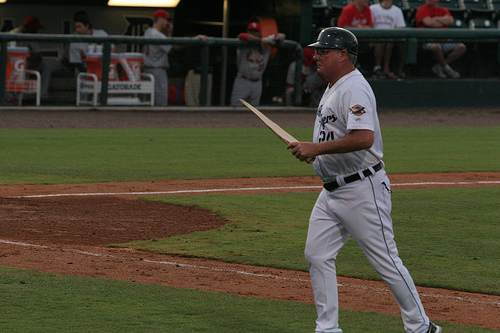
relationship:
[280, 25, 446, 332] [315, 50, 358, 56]
man wearing goggles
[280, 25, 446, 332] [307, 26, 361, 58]
man wearing helmet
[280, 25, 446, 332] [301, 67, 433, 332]
man wearing dress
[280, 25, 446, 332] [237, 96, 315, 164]
man holding wood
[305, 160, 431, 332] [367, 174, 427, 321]
pants have stripe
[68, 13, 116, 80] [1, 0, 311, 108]
player in dugout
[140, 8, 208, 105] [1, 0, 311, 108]
player in dugout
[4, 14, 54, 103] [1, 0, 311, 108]
player in dugout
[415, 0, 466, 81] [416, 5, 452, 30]
person wearing shirt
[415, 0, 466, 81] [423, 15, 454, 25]
person crosses arms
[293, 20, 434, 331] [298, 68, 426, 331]
baseball player wearing costume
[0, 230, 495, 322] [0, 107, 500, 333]
lines drawn in field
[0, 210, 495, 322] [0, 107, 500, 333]
lines drawn in field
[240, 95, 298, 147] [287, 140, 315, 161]
bat in h hand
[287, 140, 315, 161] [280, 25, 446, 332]
hand of man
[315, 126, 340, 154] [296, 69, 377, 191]
24 written on shirt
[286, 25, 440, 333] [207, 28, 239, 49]
baseball player on metal bar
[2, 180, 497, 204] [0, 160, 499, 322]
white chalk on a baseball diamond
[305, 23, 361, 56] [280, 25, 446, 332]
helmet on man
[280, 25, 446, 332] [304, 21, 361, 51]
man wearing helmet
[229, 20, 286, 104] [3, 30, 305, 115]
player leaning on rail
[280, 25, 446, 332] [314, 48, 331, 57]
man wearing goggles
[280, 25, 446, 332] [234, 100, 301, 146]
man holding stake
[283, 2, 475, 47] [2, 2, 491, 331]
spectators watch a baseball game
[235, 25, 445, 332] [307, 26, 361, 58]
man wearing helmet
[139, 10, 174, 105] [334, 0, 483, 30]
man looking at crowd